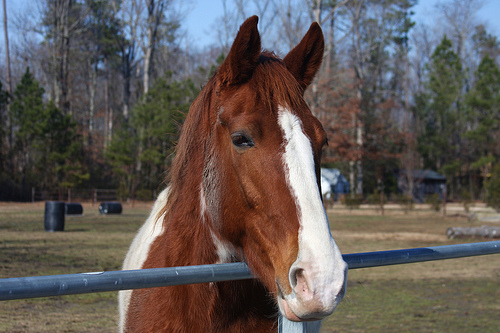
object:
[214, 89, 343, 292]
face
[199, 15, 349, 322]
head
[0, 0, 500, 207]
forest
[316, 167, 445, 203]
house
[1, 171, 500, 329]
field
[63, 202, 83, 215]
equipment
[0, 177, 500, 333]
farm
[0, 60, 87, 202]
tree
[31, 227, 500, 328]
grass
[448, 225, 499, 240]
log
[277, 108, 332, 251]
pattern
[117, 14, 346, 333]
horse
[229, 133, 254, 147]
eye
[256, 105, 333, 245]
blaze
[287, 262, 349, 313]
hose's nose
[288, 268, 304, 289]
nostril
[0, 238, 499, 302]
pole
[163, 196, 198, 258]
fur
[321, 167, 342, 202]
building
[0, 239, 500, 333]
corral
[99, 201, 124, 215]
barrel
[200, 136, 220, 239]
dirt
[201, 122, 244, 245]
cheek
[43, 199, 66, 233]
barrel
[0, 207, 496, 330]
path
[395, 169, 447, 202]
barn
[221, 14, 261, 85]
ear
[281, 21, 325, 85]
ear